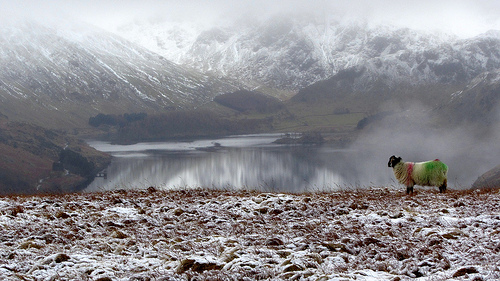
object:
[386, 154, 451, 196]
animal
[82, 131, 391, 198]
lake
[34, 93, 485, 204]
bottom of valley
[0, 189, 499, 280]
snow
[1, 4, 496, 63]
mist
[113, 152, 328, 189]
reflection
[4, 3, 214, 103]
mountains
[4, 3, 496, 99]
snow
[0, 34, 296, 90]
ridges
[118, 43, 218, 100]
smooth slope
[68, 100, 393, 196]
land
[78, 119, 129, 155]
trail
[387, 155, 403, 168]
black head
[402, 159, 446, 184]
red, white and green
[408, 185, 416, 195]
legs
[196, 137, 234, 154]
island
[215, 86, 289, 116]
plant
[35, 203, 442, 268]
brown rocks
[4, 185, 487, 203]
grass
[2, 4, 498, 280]
winter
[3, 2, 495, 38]
clouds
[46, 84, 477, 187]
fog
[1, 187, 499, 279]
ground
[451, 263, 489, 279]
rocks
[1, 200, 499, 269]
grass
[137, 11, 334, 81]
mountains